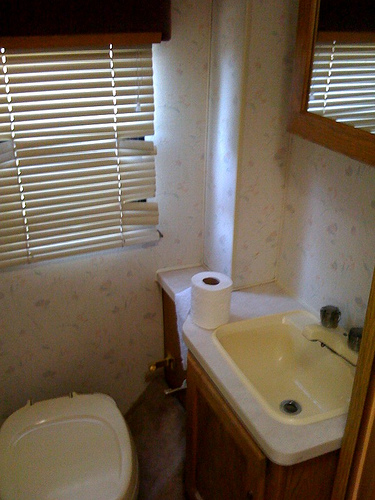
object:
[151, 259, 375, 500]
cabinet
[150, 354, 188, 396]
paper holder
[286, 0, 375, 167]
mirror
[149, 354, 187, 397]
bar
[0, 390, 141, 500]
toilet bowl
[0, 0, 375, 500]
bathroom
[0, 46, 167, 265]
sunlight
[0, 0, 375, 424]
wallpaper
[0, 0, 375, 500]
rest room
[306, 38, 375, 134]
reflection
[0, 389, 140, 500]
lid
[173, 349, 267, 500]
door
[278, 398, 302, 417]
drain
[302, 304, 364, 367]
faucet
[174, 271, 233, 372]
paper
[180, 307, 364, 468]
sink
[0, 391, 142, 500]
toilet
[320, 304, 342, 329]
handle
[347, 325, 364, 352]
handle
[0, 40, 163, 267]
blinds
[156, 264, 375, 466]
counter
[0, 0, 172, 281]
window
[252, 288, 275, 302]
part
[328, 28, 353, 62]
part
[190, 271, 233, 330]
roll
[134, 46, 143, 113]
string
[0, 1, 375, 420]
wall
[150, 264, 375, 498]
cupboard